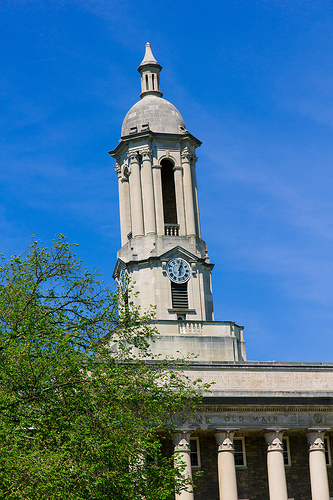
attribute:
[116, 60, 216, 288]
pillar — big, white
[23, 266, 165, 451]
trees — green, these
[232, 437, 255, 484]
windows — these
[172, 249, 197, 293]
clock — white, wall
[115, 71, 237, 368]
tower — concrete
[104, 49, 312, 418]
building — big, concrete, grey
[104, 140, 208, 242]
columns — concrete, five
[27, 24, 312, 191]
sky — blue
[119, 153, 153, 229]
pillars — these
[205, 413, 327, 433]
words — engraved